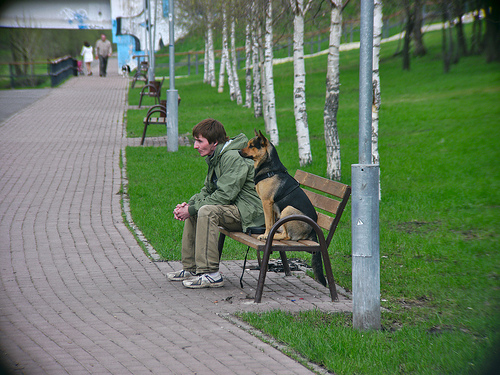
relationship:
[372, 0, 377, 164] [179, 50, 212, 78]
bark of tree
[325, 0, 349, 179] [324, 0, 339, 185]
bark of tree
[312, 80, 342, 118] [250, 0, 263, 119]
bark of tree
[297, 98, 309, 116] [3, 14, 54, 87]
bark of tree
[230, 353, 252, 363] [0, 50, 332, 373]
brick on sidewalk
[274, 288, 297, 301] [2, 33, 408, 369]
brick on sidewalk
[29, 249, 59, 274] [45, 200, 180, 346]
brick on sidewalk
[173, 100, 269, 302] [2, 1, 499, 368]
man in park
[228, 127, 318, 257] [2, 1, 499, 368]
dog in park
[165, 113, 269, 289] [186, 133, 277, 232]
man has coat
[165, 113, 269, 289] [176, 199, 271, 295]
man wearing pants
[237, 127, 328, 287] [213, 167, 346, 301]
dog on bench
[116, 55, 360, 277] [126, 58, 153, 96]
row of bench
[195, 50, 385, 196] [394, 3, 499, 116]
row of trees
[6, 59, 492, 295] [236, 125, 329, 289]
picture of dog